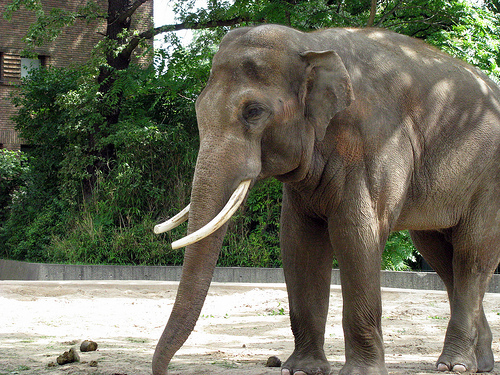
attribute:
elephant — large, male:
[123, 37, 498, 366]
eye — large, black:
[237, 98, 265, 122]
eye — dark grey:
[238, 100, 268, 122]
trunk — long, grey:
[141, 149, 323, 369]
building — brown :
[6, 7, 158, 154]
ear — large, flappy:
[305, 57, 352, 139]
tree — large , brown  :
[7, 0, 261, 196]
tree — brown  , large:
[277, 2, 497, 68]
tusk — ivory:
[146, 191, 290, 249]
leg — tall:
[324, 166, 389, 373]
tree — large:
[3, 5, 248, 261]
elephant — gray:
[96, 17, 486, 374]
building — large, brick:
[0, 3, 153, 160]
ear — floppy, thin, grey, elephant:
[305, 46, 360, 150]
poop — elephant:
[46, 333, 125, 373]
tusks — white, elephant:
[138, 189, 288, 264]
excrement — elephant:
[67, 328, 112, 370]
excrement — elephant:
[256, 340, 277, 369]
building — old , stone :
[2, 3, 160, 178]